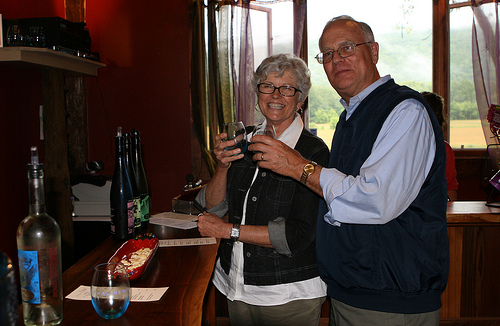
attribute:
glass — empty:
[89, 261, 131, 324]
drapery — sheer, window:
[470, 0, 498, 149]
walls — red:
[97, 1, 206, 187]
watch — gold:
[295, 156, 321, 185]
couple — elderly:
[194, 8, 455, 324]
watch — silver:
[214, 211, 251, 251]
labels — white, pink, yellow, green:
[124, 192, 149, 234]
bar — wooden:
[58, 207, 220, 324]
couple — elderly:
[183, 50, 486, 302]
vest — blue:
[320, 74, 440, 311]